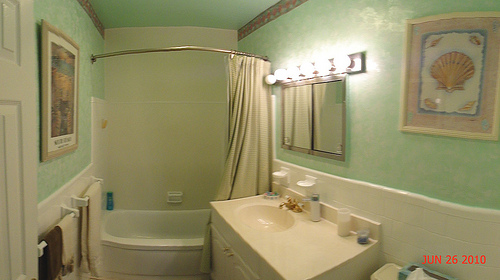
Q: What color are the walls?
A: Green.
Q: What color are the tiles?
A: White.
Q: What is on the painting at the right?
A: A seashell.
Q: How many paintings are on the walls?
A: Two.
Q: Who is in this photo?
A: Nobody.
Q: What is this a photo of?
A: A bathroom.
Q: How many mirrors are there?
A: One.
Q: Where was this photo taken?
A: The bathroom.